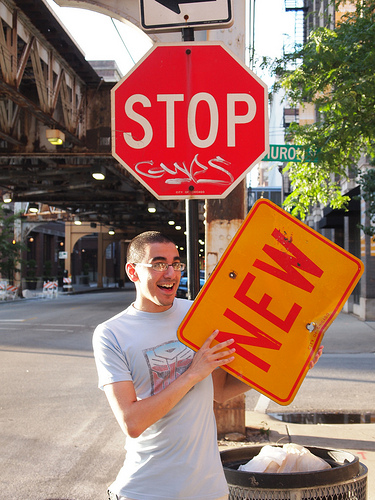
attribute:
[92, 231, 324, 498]
man — young, smiling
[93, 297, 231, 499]
shirt — white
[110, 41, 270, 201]
sign — red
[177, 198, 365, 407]
sign — orange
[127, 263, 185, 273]
glasses — wire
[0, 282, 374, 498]
road — gray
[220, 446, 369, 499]
trash can — black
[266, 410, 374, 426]
water — puddle, small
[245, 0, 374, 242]
tree — tall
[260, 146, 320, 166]
sign — green